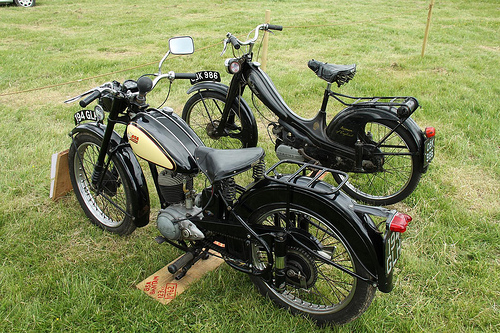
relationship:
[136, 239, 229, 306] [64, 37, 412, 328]
cardboard under bike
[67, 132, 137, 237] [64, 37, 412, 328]
wheel on bike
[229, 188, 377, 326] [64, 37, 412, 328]
wheel on bike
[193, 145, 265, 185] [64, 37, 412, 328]
seat on bike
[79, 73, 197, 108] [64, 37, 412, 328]
handlebars on bike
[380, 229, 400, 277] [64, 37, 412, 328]
plate on bike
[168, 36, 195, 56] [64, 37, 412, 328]
mirror on bike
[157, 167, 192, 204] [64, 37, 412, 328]
engine on bike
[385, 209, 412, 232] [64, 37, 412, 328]
light on bike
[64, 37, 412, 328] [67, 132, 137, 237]
bike has wheel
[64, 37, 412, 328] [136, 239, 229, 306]
bike on cardboard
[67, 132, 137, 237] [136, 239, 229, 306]
wheel on cardboard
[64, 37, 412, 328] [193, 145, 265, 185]
bike has seat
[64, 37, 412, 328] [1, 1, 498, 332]
bike on grass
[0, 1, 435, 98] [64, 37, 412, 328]
post around bike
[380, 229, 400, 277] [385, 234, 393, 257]
plate has number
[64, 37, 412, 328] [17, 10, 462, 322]
bike on grass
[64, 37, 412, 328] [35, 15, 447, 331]
bike on grass